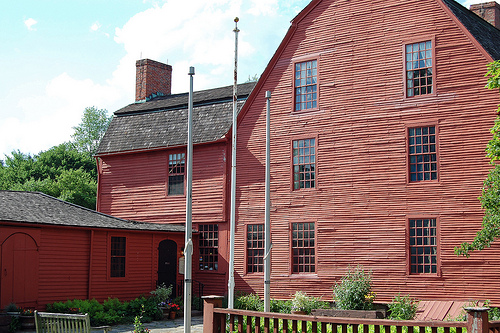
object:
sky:
[0, 0, 500, 165]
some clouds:
[7, 0, 275, 159]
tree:
[1, 101, 112, 214]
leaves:
[45, 160, 52, 166]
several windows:
[291, 35, 447, 279]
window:
[425, 85, 433, 93]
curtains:
[405, 42, 419, 95]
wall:
[97, 2, 499, 299]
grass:
[228, 298, 499, 333]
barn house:
[0, 0, 500, 332]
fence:
[198, 295, 497, 333]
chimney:
[134, 59, 171, 101]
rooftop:
[94, 82, 261, 156]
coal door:
[157, 239, 177, 299]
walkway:
[93, 314, 205, 333]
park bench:
[31, 310, 108, 332]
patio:
[2, 302, 204, 332]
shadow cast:
[148, 93, 185, 100]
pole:
[182, 66, 193, 332]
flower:
[170, 304, 175, 309]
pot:
[169, 313, 177, 320]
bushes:
[223, 244, 417, 305]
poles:
[227, 10, 241, 314]